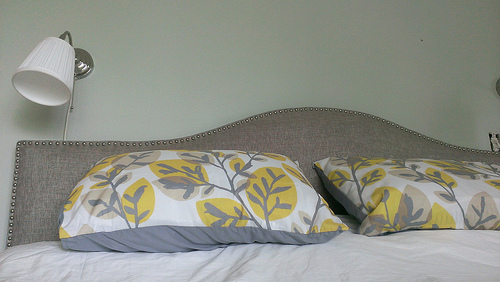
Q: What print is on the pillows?
A: Tree branches.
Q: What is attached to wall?
A: Light.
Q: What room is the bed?
A: Bedroom.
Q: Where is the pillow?
A: On a bed.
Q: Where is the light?
A: On a wall.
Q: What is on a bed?
A: A headboard.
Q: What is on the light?
A: A sconce.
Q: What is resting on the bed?
A: Pillows.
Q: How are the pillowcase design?
A: Yellow,grey and white.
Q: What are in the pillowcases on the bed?
A: Two pillows.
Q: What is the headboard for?
A: The bed.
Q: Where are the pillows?
A: On bed.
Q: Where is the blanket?
A: On bed.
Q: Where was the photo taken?
A: Bedroom.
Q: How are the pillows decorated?
A: Floral patterns.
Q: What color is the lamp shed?
A: White.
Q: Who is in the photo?
A: Nobody.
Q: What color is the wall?
A: Grey.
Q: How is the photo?
A: Clear.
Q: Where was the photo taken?
A: In a bedroom.